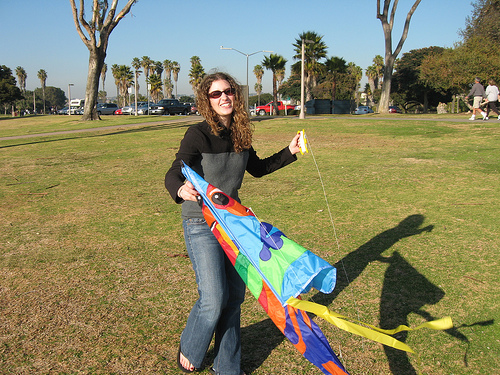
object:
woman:
[163, 71, 307, 373]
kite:
[177, 128, 453, 374]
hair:
[194, 71, 257, 158]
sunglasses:
[206, 87, 236, 99]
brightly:
[177, 157, 454, 374]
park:
[1, 1, 498, 371]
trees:
[371, 0, 423, 113]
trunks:
[80, 50, 109, 122]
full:
[48, 93, 303, 117]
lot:
[52, 92, 305, 118]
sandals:
[171, 342, 201, 373]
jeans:
[177, 209, 256, 374]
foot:
[179, 351, 201, 374]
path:
[269, 112, 499, 125]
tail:
[285, 297, 457, 354]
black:
[204, 128, 209, 153]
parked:
[253, 98, 301, 119]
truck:
[252, 99, 299, 117]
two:
[463, 75, 500, 125]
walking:
[359, 77, 500, 121]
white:
[74, 101, 82, 108]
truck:
[66, 97, 87, 115]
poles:
[241, 53, 253, 116]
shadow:
[240, 212, 497, 375]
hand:
[286, 129, 307, 155]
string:
[247, 130, 369, 374]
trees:
[67, 0, 139, 123]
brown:
[236, 118, 249, 145]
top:
[161, 117, 301, 221]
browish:
[2, 113, 499, 373]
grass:
[1, 114, 498, 347]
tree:
[279, 56, 362, 117]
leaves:
[340, 85, 352, 94]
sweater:
[160, 120, 300, 220]